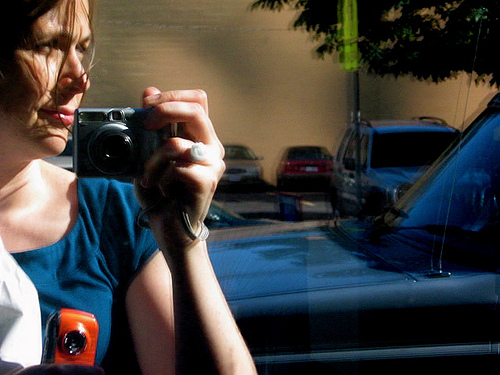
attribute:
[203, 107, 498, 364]
black vehicle — part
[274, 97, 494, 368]
vehicle — part, black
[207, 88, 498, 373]
vehicle — part, black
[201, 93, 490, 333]
vehicle — black, part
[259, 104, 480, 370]
vehicle — black, part